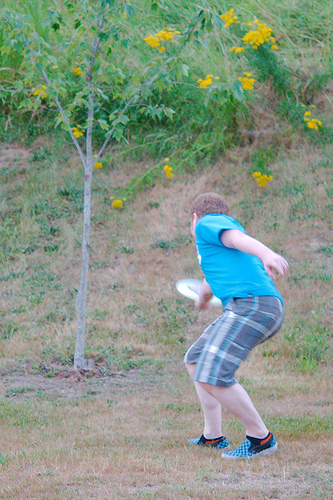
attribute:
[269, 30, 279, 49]
flower — YELLOW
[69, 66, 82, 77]
flower — YELLOW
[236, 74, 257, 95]
flower — YELLOW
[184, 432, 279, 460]
shoes — bright blue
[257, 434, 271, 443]
stripe — orange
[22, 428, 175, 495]
grass — mostly dead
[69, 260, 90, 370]
tree trunk — very thin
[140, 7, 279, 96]
flowers — yellow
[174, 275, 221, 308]
frisbee — being caught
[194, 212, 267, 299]
shirt — blue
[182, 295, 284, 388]
shorts — plaid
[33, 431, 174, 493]
grass — dry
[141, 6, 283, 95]
blossoms — yellow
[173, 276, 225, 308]
frisbee — white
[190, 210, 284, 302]
shirt — blue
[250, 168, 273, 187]
flowers — yellow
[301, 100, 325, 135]
flowers — yellow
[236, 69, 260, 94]
flowers — yellow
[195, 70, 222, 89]
flowers — yellow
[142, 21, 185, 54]
flowers — yellow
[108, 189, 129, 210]
flowers — yellow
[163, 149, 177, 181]
flowers — yellow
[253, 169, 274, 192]
flowers — yellow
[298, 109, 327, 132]
flowers — yellow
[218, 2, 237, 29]
flowers — yellow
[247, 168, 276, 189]
flower — yellow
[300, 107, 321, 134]
flower — yellow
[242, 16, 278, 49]
flower — yellow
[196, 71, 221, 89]
flower — yellow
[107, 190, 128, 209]
flower — yellow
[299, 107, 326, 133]
flower — yellow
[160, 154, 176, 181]
flower — yellow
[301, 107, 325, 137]
flower — yellow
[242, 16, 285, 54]
flower — yellow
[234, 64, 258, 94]
flower — yellow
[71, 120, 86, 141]
flower — yellow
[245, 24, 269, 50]
flower — yellow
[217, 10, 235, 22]
flower — yellow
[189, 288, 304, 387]
shorts — plaid, patterned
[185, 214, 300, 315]
shirt — bright blue colored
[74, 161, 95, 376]
trunk — thin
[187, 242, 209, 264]
emblem — white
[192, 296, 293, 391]
shorts — man's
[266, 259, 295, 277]
hand — open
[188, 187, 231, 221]
hair — short, brown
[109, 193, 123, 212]
flower — yellow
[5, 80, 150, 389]
tree — green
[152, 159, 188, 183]
flower — yellow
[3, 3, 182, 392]
tree — green